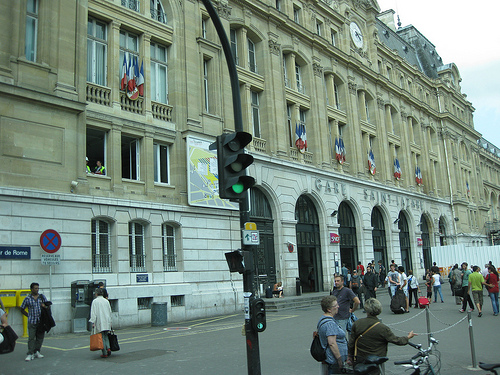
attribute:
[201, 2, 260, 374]
pole — metal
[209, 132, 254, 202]
light — green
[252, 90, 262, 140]
window — metal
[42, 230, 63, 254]
sign — blue, red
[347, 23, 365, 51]
clock — large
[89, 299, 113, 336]
jacket — white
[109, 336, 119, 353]
purse — brown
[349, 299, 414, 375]
person — standing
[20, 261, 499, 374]
people — milling